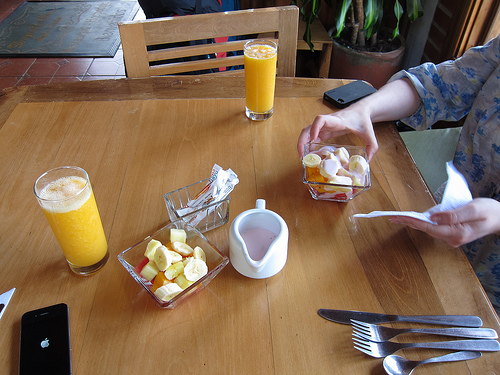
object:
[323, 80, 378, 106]
phone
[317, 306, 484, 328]
knife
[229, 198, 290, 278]
mug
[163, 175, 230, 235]
dish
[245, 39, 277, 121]
glass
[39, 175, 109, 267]
orange juice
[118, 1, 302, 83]
chair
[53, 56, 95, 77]
tile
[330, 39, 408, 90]
pot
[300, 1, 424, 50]
plant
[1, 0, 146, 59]
rug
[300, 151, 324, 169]
fruit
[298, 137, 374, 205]
bowl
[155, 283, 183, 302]
fruit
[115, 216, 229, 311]
bowl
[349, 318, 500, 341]
fork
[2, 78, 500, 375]
table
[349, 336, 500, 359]
fork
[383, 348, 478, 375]
spoon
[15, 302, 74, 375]
phone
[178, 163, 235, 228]
codiment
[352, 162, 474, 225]
napkin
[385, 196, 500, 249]
hand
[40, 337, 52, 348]
logo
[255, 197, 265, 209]
handle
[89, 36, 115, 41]
letters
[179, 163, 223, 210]
cream